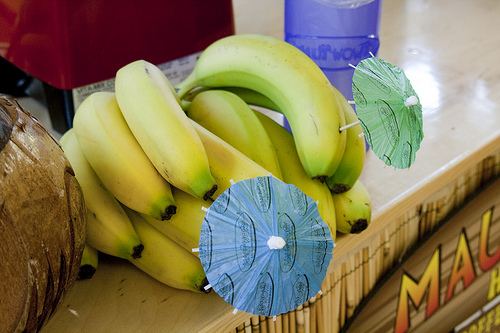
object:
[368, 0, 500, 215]
floor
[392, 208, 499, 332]
lettering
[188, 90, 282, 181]
banana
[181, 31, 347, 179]
banana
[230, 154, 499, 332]
bamboo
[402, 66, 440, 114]
light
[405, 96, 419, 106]
tip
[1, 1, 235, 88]
cloth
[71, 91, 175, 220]
banana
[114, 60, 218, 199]
banana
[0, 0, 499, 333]
counter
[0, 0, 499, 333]
counter top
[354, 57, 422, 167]
paper umbrella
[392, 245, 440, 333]
letters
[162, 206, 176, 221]
end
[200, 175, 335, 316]
umbrella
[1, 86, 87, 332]
bowl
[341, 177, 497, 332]
lettered sign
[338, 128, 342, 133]
puncture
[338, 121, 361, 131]
handle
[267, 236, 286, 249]
tip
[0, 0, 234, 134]
stand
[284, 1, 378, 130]
cup